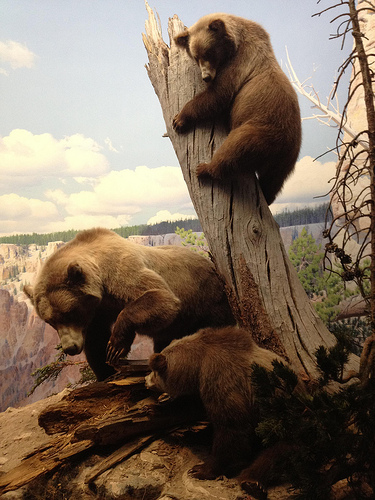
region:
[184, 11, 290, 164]
this is a bear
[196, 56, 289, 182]
the bear is on the tree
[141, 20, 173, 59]
this is the tree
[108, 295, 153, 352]
this is the limb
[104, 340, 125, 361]
these are the claws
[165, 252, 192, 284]
the bear is brown in color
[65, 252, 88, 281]
this is the ear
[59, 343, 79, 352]
this is the nose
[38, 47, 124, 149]
this is the sky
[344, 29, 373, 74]
these are the branches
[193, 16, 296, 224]
bear on the tree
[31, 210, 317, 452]
bears on the rocks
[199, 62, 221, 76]
nose of the bear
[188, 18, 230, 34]
ear of the bear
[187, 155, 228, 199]
back paw of bear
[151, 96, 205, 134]
front paw of bear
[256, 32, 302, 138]
back of the bear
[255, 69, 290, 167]
the bear is brown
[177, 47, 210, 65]
eyes of the bear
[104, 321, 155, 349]
paw of the bear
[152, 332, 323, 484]
this is a bear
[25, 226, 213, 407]
this is a bear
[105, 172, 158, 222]
this is a cloud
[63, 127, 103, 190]
this is a cloud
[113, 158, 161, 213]
this is a cloud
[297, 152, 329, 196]
this is a cloud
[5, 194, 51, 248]
this is a cloud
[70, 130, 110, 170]
this is a cloud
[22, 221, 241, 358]
This is a bear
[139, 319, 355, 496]
This is a bear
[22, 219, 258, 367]
This is a bear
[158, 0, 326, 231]
This is a bear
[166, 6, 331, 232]
This is a bear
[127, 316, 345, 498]
This is a bear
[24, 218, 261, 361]
This is a bear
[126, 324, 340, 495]
This is a bear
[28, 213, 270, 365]
This is a bear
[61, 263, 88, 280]
Ear of a bear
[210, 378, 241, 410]
Fur on a bear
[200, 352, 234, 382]
Fur on a bear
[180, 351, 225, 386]
Fur on a bear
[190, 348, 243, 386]
Fur on a bear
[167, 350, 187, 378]
Fur on a bear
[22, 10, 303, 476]
three dark bears on hill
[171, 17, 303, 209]
small dark bear around brown stem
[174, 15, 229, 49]
small fury ears of bear in brown stem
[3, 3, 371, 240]
light blue clear sky with white clouds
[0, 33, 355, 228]
white clouds in sky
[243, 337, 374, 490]
small green bushes in the corner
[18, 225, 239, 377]
big brown bear behind stem